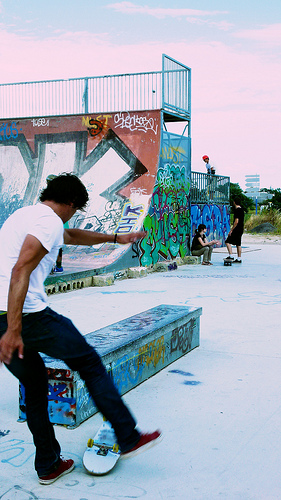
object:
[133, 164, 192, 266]
graffiti art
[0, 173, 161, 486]
man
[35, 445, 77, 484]
sneakers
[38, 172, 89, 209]
hair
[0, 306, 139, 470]
jeans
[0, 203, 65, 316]
shirt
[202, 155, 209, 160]
helmet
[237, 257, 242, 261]
socks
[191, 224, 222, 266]
woman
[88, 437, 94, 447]
wheel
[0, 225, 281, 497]
ground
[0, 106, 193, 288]
wall